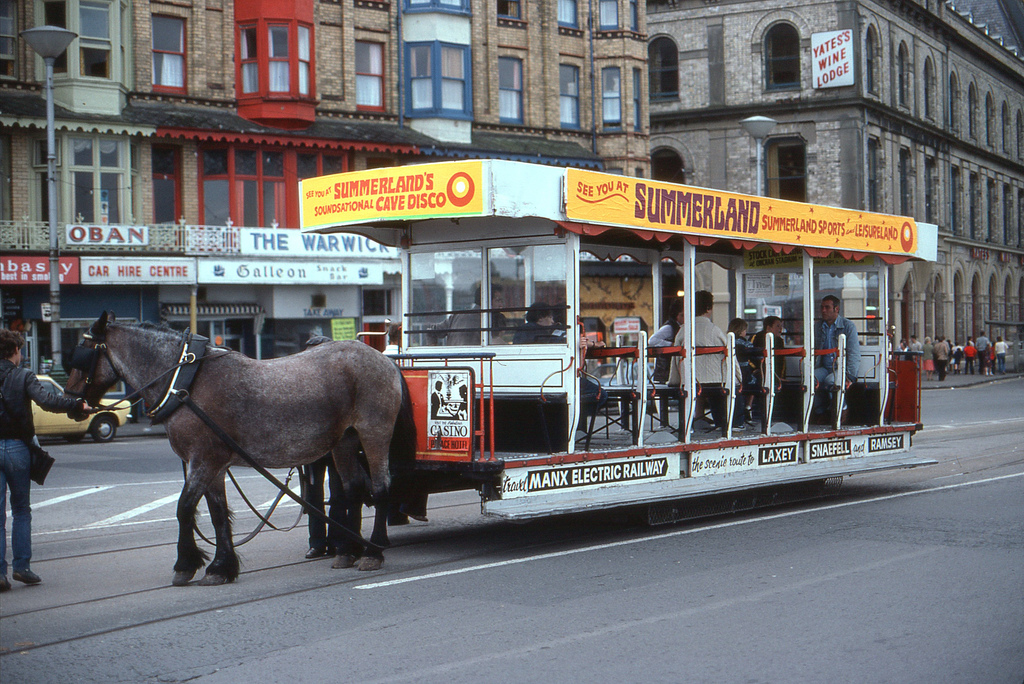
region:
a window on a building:
[78, 10, 105, 71]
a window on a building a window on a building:
[152, 7, 194, 94]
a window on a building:
[240, 17, 308, 109]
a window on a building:
[402, 28, 467, 117]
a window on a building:
[493, 51, 522, 116]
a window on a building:
[563, 48, 577, 131]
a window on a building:
[591, 66, 630, 127]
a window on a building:
[60, 139, 131, 220]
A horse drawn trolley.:
[62, 157, 936, 582]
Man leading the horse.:
[0, 320, 92, 583]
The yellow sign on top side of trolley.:
[563, 165, 911, 249]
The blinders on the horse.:
[64, 333, 106, 376]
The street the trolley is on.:
[1, 377, 1017, 676]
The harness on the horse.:
[140, 323, 207, 419]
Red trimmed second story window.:
[228, 0, 309, 121]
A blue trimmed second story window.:
[399, 35, 466, 115]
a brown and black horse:
[57, 320, 427, 578]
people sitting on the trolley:
[629, 277, 860, 402]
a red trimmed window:
[231, 2, 326, 121]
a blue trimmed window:
[403, 29, 479, 134]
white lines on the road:
[38, 459, 362, 539]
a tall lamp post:
[25, 12, 96, 452]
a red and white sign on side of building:
[812, 26, 855, 94]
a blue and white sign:
[243, 231, 398, 267]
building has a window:
[96, 137, 119, 224]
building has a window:
[197, 142, 227, 223]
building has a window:
[150, 137, 180, 218]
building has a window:
[269, 22, 290, 95]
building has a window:
[295, 26, 314, 93]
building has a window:
[358, 38, 385, 108]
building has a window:
[405, 47, 429, 108]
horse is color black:
[59, 321, 413, 577]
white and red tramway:
[294, 173, 953, 528]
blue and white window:
[402, 11, 473, 145]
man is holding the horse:
[0, 329, 84, 596]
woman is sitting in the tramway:
[670, 290, 744, 428]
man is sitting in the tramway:
[805, 290, 859, 428]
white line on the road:
[85, 467, 213, 532]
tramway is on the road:
[299, 146, 966, 557]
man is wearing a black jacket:
[5, 355, 92, 451]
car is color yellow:
[0, 371, 136, 448]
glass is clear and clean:
[150, 11, 183, 46]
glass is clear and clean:
[154, 56, 186, 82]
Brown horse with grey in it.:
[62, 309, 436, 594]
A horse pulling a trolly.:
[62, 303, 440, 585]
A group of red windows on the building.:
[151, 121, 436, 240]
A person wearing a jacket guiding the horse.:
[3, 316, 99, 601]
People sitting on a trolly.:
[287, 155, 945, 530]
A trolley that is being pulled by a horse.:
[284, 154, 945, 538]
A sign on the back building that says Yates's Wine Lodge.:
[802, 22, 867, 98]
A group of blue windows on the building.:
[389, 7, 650, 147]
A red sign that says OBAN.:
[62, 217, 154, 255]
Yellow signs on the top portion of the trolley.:
[280, 155, 948, 267]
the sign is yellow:
[298, 159, 476, 227]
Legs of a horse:
[148, 458, 257, 592]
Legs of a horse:
[324, 442, 401, 575]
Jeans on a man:
[2, 435, 56, 595]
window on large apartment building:
[77, 0, 113, 79]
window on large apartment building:
[551, 59, 572, 117]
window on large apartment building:
[492, 52, 521, 119]